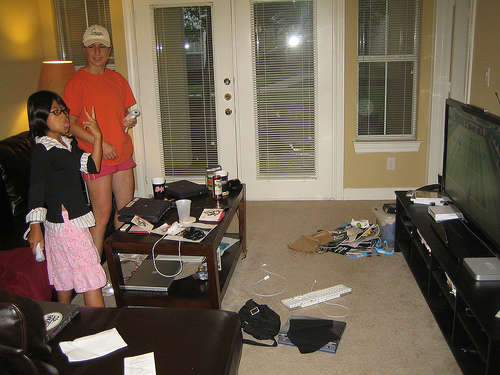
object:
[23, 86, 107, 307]
girl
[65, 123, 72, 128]
tounge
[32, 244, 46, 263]
wii remote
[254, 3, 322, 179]
blinds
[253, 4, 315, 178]
door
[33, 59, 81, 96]
lamp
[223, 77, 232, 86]
locks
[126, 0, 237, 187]
door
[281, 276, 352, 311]
keyboard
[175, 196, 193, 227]
cup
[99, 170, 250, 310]
table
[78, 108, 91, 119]
finger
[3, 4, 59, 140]
wall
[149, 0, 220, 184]
window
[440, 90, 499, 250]
tv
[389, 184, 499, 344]
table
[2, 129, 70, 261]
couch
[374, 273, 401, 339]
floor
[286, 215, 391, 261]
pile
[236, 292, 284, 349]
bags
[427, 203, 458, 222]
game system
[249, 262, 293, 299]
cord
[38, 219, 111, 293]
skirt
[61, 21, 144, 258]
woman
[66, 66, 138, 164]
shirt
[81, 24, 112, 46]
hat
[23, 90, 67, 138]
hair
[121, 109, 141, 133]
wii remote